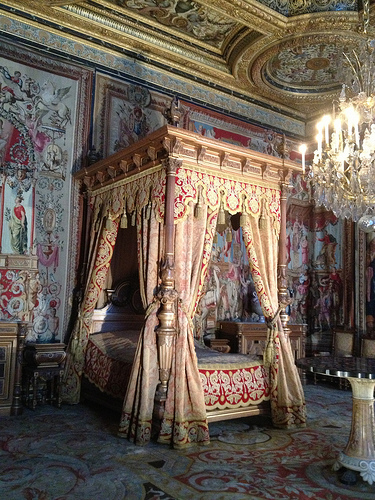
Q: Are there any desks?
A: Yes, there is a desk.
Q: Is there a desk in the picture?
A: Yes, there is a desk.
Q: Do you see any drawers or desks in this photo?
A: Yes, there is a desk.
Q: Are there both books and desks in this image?
A: No, there is a desk but no books.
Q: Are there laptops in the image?
A: No, there are no laptops.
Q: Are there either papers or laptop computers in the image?
A: No, there are no laptop computers or papers.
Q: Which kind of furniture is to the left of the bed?
A: The piece of furniture is a desk.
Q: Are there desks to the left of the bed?
A: Yes, there is a desk to the left of the bed.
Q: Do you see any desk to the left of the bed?
A: Yes, there is a desk to the left of the bed.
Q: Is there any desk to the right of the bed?
A: No, the desk is to the left of the bed.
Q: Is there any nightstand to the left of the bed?
A: No, there is a desk to the left of the bed.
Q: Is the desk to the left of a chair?
A: No, the desk is to the left of the bed.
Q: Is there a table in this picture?
A: Yes, there is a table.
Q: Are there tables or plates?
A: Yes, there is a table.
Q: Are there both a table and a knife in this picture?
A: No, there is a table but no knives.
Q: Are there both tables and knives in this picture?
A: No, there is a table but no knives.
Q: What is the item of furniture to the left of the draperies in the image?
A: The piece of furniture is a table.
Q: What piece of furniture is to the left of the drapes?
A: The piece of furniture is a table.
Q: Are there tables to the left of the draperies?
A: Yes, there is a table to the left of the draperies.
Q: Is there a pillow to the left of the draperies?
A: No, there is a table to the left of the draperies.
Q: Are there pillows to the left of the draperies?
A: No, there is a table to the left of the draperies.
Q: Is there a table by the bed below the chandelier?
A: Yes, there is a table by the bed.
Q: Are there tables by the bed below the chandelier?
A: Yes, there is a table by the bed.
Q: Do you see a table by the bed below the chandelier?
A: Yes, there is a table by the bed.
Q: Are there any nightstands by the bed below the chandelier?
A: No, there is a table by the bed.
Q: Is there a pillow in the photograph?
A: No, there are no pillows.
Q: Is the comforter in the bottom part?
A: Yes, the comforter is in the bottom of the image.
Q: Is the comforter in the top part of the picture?
A: No, the comforter is in the bottom of the image.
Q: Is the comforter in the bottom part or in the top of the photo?
A: The comforter is in the bottom of the image.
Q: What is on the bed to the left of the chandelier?
A: The quilt is on the bed.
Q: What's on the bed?
A: The quilt is on the bed.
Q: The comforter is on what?
A: The comforter is on the bed.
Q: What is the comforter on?
A: The comforter is on the bed.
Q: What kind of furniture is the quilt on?
A: The quilt is on the bed.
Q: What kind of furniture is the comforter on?
A: The quilt is on the bed.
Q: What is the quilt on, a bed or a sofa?
A: The quilt is on a bed.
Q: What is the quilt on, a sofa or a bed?
A: The quilt is on a bed.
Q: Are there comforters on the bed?
A: Yes, there is a comforter on the bed.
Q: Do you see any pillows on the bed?
A: No, there is a comforter on the bed.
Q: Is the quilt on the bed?
A: Yes, the quilt is on the bed.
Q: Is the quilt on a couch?
A: No, the quilt is on the bed.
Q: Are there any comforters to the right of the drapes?
A: Yes, there is a comforter to the right of the drapes.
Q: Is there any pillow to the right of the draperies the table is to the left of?
A: No, there is a comforter to the right of the draperies.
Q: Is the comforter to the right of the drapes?
A: Yes, the comforter is to the right of the drapes.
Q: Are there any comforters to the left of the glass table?
A: Yes, there is a comforter to the left of the table.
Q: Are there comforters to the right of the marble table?
A: No, the comforter is to the left of the table.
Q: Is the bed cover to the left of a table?
A: Yes, the bed cover is to the left of a table.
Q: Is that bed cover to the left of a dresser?
A: No, the bed cover is to the left of a table.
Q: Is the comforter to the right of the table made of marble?
A: No, the comforter is to the left of the table.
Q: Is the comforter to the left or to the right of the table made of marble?
A: The comforter is to the left of the table.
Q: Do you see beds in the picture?
A: Yes, there is a bed.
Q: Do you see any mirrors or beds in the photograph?
A: Yes, there is a bed.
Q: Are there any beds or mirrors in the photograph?
A: Yes, there is a bed.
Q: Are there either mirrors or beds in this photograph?
A: Yes, there is a bed.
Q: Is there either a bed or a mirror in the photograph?
A: Yes, there is a bed.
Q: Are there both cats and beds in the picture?
A: No, there is a bed but no cats.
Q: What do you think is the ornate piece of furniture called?
A: The piece of furniture is a bed.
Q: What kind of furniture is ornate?
A: The furniture is a bed.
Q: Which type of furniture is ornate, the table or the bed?
A: The bed is ornate.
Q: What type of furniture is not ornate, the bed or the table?
A: The table is not ornate.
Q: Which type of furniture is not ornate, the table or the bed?
A: The table is not ornate.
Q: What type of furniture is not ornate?
A: The furniture is a table.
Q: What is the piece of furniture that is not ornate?
A: The piece of furniture is a table.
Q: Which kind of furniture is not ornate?
A: The furniture is a table.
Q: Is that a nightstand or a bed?
A: That is a bed.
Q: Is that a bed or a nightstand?
A: That is a bed.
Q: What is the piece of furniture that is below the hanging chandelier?
A: The piece of furniture is a bed.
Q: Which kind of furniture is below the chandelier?
A: The piece of furniture is a bed.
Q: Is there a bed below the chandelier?
A: Yes, there is a bed below the chandelier.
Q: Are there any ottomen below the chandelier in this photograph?
A: No, there is a bed below the chandelier.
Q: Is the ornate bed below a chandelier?
A: Yes, the bed is below a chandelier.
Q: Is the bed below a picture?
A: No, the bed is below a chandelier.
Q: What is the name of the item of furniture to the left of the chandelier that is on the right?
A: The piece of furniture is a bed.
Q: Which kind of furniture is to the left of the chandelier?
A: The piece of furniture is a bed.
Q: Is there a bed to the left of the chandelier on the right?
A: Yes, there is a bed to the left of the chandelier.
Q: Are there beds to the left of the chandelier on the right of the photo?
A: Yes, there is a bed to the left of the chandelier.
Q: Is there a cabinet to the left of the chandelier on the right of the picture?
A: No, there is a bed to the left of the chandelier.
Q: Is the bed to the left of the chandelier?
A: Yes, the bed is to the left of the chandelier.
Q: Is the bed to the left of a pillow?
A: No, the bed is to the left of the chandelier.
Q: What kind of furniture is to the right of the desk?
A: The piece of furniture is a bed.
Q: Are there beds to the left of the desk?
A: No, the bed is to the right of the desk.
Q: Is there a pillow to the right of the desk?
A: No, there is a bed to the right of the desk.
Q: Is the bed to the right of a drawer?
A: No, the bed is to the right of the desk.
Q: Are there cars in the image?
A: No, there are no cars.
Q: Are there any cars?
A: No, there are no cars.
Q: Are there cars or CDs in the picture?
A: No, there are no cars or cds.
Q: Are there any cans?
A: No, there are no cans.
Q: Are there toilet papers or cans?
A: No, there are no cans or toilet papers.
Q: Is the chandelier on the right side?
A: Yes, the chandelier is on the right of the image.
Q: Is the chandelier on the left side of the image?
A: No, the chandelier is on the right of the image.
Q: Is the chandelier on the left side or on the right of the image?
A: The chandelier is on the right of the image.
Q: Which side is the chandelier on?
A: The chandelier is on the right of the image.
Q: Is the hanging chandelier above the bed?
A: Yes, the chandelier is above the bed.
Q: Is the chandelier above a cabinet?
A: No, the chandelier is above the bed.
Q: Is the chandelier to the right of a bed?
A: Yes, the chandelier is to the right of a bed.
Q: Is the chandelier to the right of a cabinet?
A: No, the chandelier is to the right of a bed.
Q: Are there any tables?
A: Yes, there is a table.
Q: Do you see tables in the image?
A: Yes, there is a table.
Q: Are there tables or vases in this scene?
A: Yes, there is a table.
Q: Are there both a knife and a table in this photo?
A: No, there is a table but no knives.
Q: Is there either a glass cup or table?
A: Yes, there is a glass table.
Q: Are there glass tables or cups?
A: Yes, there is a glass table.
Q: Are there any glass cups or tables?
A: Yes, there is a glass table.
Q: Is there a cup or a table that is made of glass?
A: Yes, the table is made of glass.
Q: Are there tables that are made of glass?
A: Yes, there is a table that is made of glass.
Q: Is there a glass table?
A: Yes, there is a table that is made of glass.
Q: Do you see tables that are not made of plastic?
A: Yes, there is a table that is made of glass.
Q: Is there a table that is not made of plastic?
A: Yes, there is a table that is made of glass.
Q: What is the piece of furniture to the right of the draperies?
A: The piece of furniture is a table.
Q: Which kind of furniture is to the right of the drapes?
A: The piece of furniture is a table.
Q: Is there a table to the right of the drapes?
A: Yes, there is a table to the right of the drapes.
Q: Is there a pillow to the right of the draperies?
A: No, there is a table to the right of the draperies.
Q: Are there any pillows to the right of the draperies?
A: No, there is a table to the right of the draperies.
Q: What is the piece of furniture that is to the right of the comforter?
A: The piece of furniture is a table.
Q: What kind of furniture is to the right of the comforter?
A: The piece of furniture is a table.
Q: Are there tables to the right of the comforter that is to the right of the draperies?
A: Yes, there is a table to the right of the comforter.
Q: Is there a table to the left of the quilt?
A: No, the table is to the right of the quilt.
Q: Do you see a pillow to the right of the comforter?
A: No, there is a table to the right of the comforter.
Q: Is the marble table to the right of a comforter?
A: Yes, the table is to the right of a comforter.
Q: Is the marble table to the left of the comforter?
A: No, the table is to the right of the comforter.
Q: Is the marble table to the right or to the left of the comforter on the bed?
A: The table is to the right of the comforter.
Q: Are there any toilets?
A: No, there are no toilets.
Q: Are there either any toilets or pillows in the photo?
A: No, there are no toilets or pillows.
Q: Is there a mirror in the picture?
A: No, there are no mirrors.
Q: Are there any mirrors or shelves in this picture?
A: No, there are no mirrors or shelves.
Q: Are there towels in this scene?
A: No, there are no towels.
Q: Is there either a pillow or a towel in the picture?
A: No, there are no towels or pillows.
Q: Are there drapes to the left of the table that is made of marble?
A: Yes, there are drapes to the left of the table.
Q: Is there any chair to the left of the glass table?
A: No, there are drapes to the left of the table.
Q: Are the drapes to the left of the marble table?
A: Yes, the drapes are to the left of the table.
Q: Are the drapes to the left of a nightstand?
A: No, the drapes are to the left of the table.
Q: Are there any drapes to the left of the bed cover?
A: Yes, there are drapes to the left of the bed cover.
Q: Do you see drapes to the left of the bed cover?
A: Yes, there are drapes to the left of the bed cover.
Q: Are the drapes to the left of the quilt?
A: Yes, the drapes are to the left of the quilt.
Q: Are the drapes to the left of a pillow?
A: No, the drapes are to the left of the quilt.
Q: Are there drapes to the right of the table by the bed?
A: Yes, there are drapes to the right of the table.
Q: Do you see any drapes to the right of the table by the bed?
A: Yes, there are drapes to the right of the table.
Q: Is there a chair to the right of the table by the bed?
A: No, there are drapes to the right of the table.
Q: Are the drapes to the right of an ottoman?
A: No, the drapes are to the right of the table.